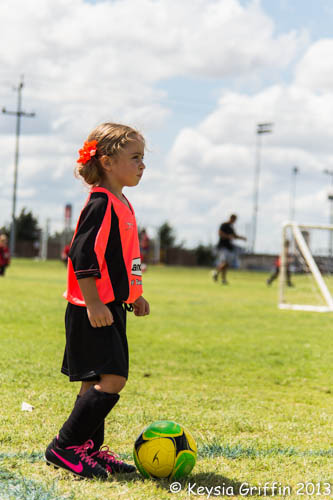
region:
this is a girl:
[36, 111, 167, 489]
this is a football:
[129, 414, 196, 480]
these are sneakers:
[38, 426, 132, 492]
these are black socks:
[49, 383, 119, 440]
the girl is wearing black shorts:
[43, 297, 142, 383]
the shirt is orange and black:
[64, 183, 143, 309]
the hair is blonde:
[70, 113, 155, 190]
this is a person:
[205, 188, 243, 288]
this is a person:
[255, 222, 291, 294]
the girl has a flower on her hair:
[69, 138, 105, 173]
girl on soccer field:
[55, 119, 178, 431]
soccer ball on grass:
[127, 416, 208, 488]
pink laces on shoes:
[71, 438, 103, 470]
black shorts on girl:
[52, 297, 139, 384]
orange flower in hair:
[74, 138, 102, 168]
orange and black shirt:
[63, 198, 144, 312]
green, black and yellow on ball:
[135, 418, 184, 456]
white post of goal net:
[272, 219, 307, 314]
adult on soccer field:
[198, 207, 256, 292]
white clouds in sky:
[153, 40, 226, 78]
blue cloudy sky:
[0, 0, 331, 255]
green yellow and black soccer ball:
[133, 418, 197, 482]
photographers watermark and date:
[168, 479, 332, 498]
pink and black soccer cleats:
[42, 431, 137, 482]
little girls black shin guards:
[48, 386, 120, 454]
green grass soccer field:
[0, 256, 331, 498]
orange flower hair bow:
[75, 138, 97, 164]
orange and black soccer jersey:
[61, 185, 142, 307]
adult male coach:
[209, 212, 248, 286]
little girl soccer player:
[45, 119, 152, 479]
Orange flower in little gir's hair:
[74, 138, 100, 167]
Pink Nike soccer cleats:
[41, 437, 137, 484]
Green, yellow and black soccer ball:
[130, 417, 199, 482]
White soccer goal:
[275, 218, 332, 319]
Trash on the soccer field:
[14, 393, 37, 416]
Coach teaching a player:
[204, 206, 251, 289]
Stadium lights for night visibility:
[245, 113, 276, 265]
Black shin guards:
[43, 385, 123, 457]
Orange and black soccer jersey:
[55, 187, 161, 313]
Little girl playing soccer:
[39, 117, 203, 482]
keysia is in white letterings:
[184, 479, 232, 496]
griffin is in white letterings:
[237, 478, 292, 498]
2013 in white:
[296, 480, 331, 499]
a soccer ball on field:
[131, 418, 200, 482]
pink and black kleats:
[42, 433, 136, 479]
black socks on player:
[57, 387, 121, 447]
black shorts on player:
[58, 300, 132, 383]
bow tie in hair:
[75, 137, 97, 168]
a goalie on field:
[275, 218, 332, 319]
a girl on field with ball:
[43, 118, 198, 485]